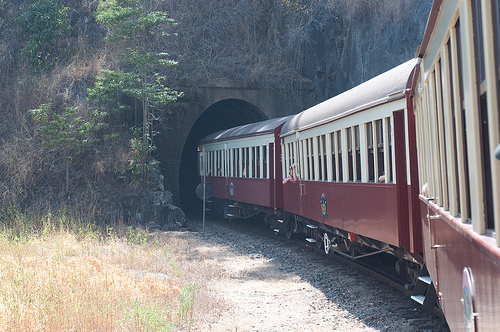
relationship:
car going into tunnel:
[195, 0, 498, 332] [139, 86, 314, 218]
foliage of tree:
[98, 0, 181, 110] [2, 1, 182, 219]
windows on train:
[172, 132, 441, 221] [158, 88, 487, 273]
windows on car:
[228, 147, 268, 176] [195, 0, 498, 332]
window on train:
[323, 132, 342, 176] [194, 94, 433, 276]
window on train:
[343, 124, 357, 178] [194, 94, 433, 276]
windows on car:
[403, 35, 498, 205] [195, 0, 498, 332]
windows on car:
[194, 145, 274, 182] [195, 0, 498, 332]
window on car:
[471, 3, 494, 231] [195, 0, 498, 332]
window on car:
[453, 17, 468, 234] [195, 0, 498, 332]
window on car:
[435, 39, 452, 214] [195, 0, 498, 332]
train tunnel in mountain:
[178, 98, 270, 221] [3, 0, 495, 311]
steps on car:
[409, 261, 438, 311] [195, 0, 498, 332]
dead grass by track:
[68, 256, 140, 307] [209, 214, 445, 313]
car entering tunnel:
[195, 0, 498, 332] [173, 90, 278, 237]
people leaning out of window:
[270, 152, 325, 213] [277, 139, 306, 184]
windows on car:
[337, 119, 365, 191] [195, 0, 498, 332]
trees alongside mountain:
[12, 0, 183, 230] [1, 1, 435, 221]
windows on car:
[284, 119, 391, 187] [195, 0, 498, 332]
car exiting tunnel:
[195, 0, 498, 332] [177, 88, 277, 228]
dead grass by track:
[0, 227, 183, 331] [206, 220, 446, 325]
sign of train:
[285, 177, 343, 234] [164, 68, 497, 275]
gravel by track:
[166, 221, 404, 329] [209, 214, 445, 313]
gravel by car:
[166, 221, 404, 329] [195, 0, 498, 332]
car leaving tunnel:
[195, 0, 498, 332] [234, 55, 283, 293]